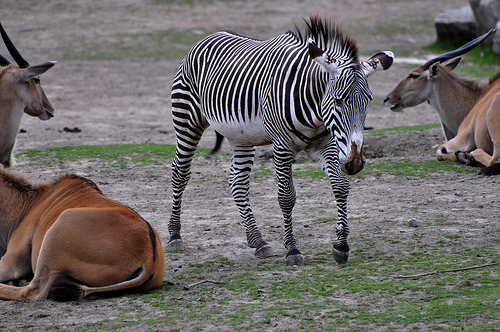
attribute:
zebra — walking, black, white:
[158, 15, 396, 270]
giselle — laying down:
[385, 28, 499, 174]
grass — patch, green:
[17, 140, 174, 173]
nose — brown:
[349, 141, 360, 173]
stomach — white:
[204, 111, 270, 147]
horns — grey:
[420, 27, 498, 67]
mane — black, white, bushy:
[292, 14, 361, 63]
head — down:
[305, 36, 395, 176]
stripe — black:
[234, 153, 256, 158]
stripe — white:
[233, 157, 254, 162]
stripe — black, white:
[172, 118, 201, 137]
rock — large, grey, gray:
[434, 4, 478, 50]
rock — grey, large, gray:
[467, 0, 500, 52]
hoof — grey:
[331, 246, 350, 265]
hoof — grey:
[284, 256, 306, 269]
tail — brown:
[50, 273, 149, 304]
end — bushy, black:
[49, 279, 84, 305]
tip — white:
[307, 38, 316, 44]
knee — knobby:
[276, 182, 297, 208]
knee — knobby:
[327, 175, 350, 197]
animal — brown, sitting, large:
[1, 160, 167, 302]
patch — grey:
[55, 61, 169, 143]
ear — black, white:
[360, 47, 396, 76]